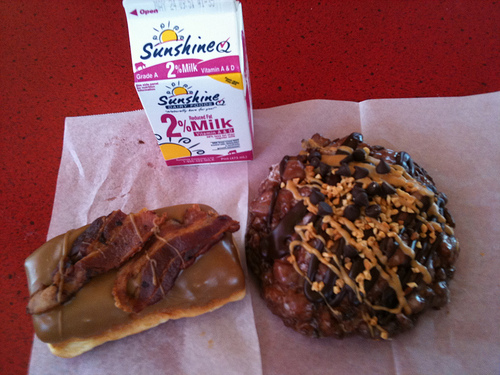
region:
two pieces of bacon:
[57, 237, 191, 285]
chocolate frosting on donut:
[42, 249, 246, 322]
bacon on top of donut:
[32, 233, 229, 302]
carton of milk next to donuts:
[135, 11, 264, 156]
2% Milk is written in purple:
[165, 107, 239, 144]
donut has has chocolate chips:
[326, 136, 400, 221]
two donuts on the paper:
[85, 195, 400, 329]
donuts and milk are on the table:
[27, 93, 332, 213]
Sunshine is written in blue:
[146, 45, 224, 63]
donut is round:
[262, 146, 431, 339]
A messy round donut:
[255, 146, 453, 335]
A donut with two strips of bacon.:
[30, 208, 245, 327]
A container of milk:
[124, 5, 261, 157]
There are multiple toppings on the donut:
[256, 137, 457, 330]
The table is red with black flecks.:
[258, 4, 497, 88]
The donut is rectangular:
[21, 207, 245, 359]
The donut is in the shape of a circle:
[258, 141, 456, 338]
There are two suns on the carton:
[141, 82, 258, 165]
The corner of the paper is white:
[67, 117, 136, 180]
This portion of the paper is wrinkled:
[211, 317, 282, 372]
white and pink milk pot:
[124, 2, 262, 170]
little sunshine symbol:
[154, 19, 182, 50]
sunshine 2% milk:
[121, 2, 258, 170]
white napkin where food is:
[22, 105, 497, 369]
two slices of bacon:
[21, 205, 241, 325]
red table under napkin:
[10, 2, 497, 371]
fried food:
[31, 134, 462, 342]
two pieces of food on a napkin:
[27, 137, 464, 341]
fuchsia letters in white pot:
[160, 107, 245, 152]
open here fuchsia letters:
[128, 0, 168, 25]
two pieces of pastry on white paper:
[24, 142, 469, 373]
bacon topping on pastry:
[22, 222, 236, 327]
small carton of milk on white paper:
[71, 0, 308, 178]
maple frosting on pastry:
[17, 225, 251, 334]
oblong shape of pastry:
[7, 212, 267, 345]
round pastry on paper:
[252, 145, 497, 370]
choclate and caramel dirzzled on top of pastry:
[262, 150, 452, 335]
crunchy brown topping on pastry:
[259, 142, 463, 335]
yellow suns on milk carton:
[148, 38, 240, 173]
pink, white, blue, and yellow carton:
[135, 62, 287, 193]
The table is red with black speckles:
[287, 10, 446, 109]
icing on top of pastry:
[242, 153, 418, 287]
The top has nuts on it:
[302, 152, 379, 253]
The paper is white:
[417, 298, 478, 363]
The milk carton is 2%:
[110, 31, 301, 187]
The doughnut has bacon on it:
[12, 223, 284, 320]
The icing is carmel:
[49, 253, 102, 326]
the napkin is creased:
[350, 60, 372, 136]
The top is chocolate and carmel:
[285, 182, 388, 287]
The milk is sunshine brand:
[123, 24, 245, 52]